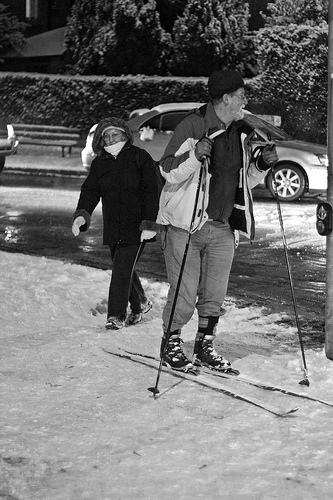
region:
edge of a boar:
[231, 381, 260, 419]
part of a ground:
[101, 437, 134, 477]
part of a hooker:
[148, 365, 170, 404]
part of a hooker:
[154, 332, 184, 380]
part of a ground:
[132, 460, 134, 462]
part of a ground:
[103, 400, 136, 448]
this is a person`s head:
[58, 107, 146, 169]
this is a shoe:
[157, 327, 195, 376]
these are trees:
[75, 1, 323, 87]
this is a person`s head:
[202, 67, 266, 130]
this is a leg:
[92, 225, 163, 329]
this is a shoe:
[99, 312, 125, 332]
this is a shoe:
[122, 293, 153, 330]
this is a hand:
[68, 157, 104, 239]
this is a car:
[82, 94, 325, 199]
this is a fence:
[0, 67, 225, 124]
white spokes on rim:
[281, 167, 287, 174]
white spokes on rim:
[282, 183, 286, 186]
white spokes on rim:
[270, 179, 273, 184]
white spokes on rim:
[269, 174, 273, 176]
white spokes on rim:
[286, 170, 294, 175]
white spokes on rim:
[271, 167, 297, 196]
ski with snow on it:
[119, 344, 328, 408]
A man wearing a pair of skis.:
[101, 67, 332, 417]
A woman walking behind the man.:
[72, 116, 157, 330]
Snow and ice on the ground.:
[0, 139, 331, 499]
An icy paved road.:
[0, 185, 332, 347]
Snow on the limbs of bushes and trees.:
[0, 0, 332, 144]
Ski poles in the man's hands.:
[148, 130, 309, 398]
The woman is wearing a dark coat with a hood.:
[71, 115, 159, 241]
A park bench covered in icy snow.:
[6, 122, 78, 158]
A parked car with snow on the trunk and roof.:
[81, 103, 332, 202]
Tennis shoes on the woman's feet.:
[104, 296, 151, 329]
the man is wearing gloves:
[193, 131, 279, 170]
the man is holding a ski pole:
[255, 144, 315, 385]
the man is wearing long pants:
[155, 218, 238, 339]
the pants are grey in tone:
[164, 224, 231, 335]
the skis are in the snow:
[104, 339, 326, 423]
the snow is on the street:
[1, 248, 328, 498]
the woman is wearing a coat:
[76, 113, 164, 250]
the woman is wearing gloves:
[70, 214, 160, 243]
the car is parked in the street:
[79, 99, 329, 208]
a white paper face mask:
[105, 144, 126, 156]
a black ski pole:
[154, 178, 198, 402]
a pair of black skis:
[96, 337, 325, 421]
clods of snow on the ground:
[2, 406, 70, 498]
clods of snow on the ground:
[73, 415, 152, 494]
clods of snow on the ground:
[241, 422, 329, 498]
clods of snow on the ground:
[2, 343, 50, 400]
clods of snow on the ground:
[51, 343, 120, 408]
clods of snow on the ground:
[3, 307, 46, 335]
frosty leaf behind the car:
[284, 102, 289, 110]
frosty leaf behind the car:
[300, 122, 305, 129]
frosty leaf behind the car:
[303, 105, 307, 112]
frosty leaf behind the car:
[312, 102, 314, 106]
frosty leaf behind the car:
[293, 93, 294, 101]